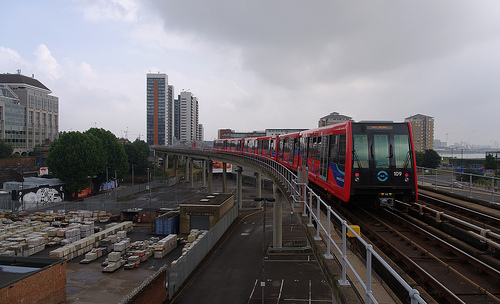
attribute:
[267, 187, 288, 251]
pole — concrete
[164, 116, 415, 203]
train — passenger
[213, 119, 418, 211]
train — red 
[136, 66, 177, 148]
building — multi-story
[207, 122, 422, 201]
train — red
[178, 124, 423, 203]
train — red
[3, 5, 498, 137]
sky — blue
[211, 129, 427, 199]
train — passenger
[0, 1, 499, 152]
sky — cloudy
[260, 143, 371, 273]
railing — metal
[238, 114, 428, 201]
train — moving